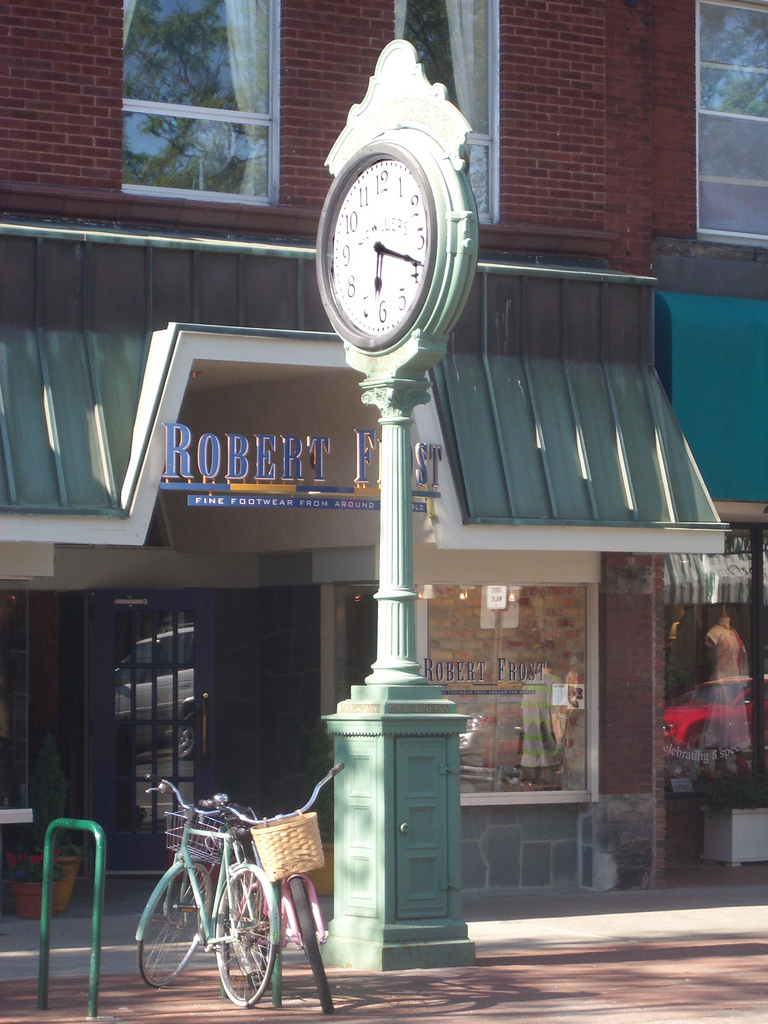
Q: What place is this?
A: It is a shop.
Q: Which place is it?
A: It is a shop.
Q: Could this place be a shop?
A: Yes, it is a shop.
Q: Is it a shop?
A: Yes, it is a shop.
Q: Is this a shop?
A: Yes, it is a shop.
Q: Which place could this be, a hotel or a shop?
A: It is a shop.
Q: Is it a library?
A: No, it is a shop.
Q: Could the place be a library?
A: No, it is a shop.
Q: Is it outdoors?
A: Yes, it is outdoors.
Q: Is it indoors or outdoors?
A: It is outdoors.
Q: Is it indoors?
A: No, it is outdoors.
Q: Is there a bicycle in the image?
A: Yes, there is a bicycle.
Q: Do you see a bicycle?
A: Yes, there is a bicycle.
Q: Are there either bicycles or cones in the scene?
A: Yes, there is a bicycle.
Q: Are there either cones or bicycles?
A: Yes, there is a bicycle.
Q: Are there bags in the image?
A: No, there are no bags.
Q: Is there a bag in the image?
A: No, there are no bags.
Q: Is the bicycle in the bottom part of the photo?
A: Yes, the bicycle is in the bottom of the image.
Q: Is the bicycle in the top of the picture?
A: No, the bicycle is in the bottom of the image.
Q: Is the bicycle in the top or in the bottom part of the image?
A: The bicycle is in the bottom of the image.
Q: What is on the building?
A: The sign is on the building.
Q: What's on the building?
A: The sign is on the building.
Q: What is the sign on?
A: The sign is on the building.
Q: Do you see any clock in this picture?
A: Yes, there is a clock.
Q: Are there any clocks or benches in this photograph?
A: Yes, there is a clock.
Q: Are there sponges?
A: No, there are no sponges.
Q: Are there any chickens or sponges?
A: No, there are no sponges or chickens.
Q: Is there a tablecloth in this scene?
A: No, there are no tablecloths.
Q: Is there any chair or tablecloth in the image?
A: No, there are no tablecloths or chairs.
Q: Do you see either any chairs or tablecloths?
A: No, there are no tablecloths or chairs.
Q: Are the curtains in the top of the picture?
A: Yes, the curtains are in the top of the image.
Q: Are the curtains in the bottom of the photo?
A: No, the curtains are in the top of the image.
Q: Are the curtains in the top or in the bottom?
A: The curtains are in the top of the image.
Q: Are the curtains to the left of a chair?
A: No, the curtains are to the left of the clock.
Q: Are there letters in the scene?
A: Yes, there are letters.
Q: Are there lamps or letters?
A: Yes, there are letters.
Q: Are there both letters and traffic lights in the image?
A: No, there are letters but no traffic lights.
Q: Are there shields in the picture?
A: No, there are no shields.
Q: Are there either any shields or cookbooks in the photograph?
A: No, there are no shields or cookbooks.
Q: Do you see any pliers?
A: No, there are no pliers.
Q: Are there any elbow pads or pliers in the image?
A: No, there are no pliers or elbow pads.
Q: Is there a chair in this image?
A: No, there are no chairs.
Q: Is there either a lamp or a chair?
A: No, there are no chairs or lamps.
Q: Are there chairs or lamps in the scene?
A: No, there are no chairs or lamps.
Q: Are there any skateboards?
A: No, there are no skateboards.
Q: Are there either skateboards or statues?
A: No, there are no skateboards or statues.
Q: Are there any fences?
A: No, there are no fences.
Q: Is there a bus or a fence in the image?
A: No, there are no fences or buses.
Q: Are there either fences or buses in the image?
A: No, there are no fences or buses.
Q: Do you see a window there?
A: Yes, there is a window.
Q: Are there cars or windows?
A: Yes, there is a window.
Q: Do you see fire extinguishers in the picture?
A: No, there are no fire extinguishers.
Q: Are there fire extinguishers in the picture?
A: No, there are no fire extinguishers.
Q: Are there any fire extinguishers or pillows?
A: No, there are no fire extinguishers or pillows.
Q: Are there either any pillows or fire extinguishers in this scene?
A: No, there are no fire extinguishers or pillows.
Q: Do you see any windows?
A: Yes, there is a window.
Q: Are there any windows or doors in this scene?
A: Yes, there is a window.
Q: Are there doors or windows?
A: Yes, there is a window.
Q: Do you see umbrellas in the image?
A: No, there are no umbrellas.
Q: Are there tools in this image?
A: No, there are no tools.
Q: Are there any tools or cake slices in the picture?
A: No, there are no tools or cake slices.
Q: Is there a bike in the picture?
A: Yes, there are bikes.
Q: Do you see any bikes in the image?
A: Yes, there are bikes.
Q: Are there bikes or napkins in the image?
A: Yes, there are bikes.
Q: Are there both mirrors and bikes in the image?
A: No, there are bikes but no mirrors.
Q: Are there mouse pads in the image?
A: No, there are no mouse pads.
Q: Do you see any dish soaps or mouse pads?
A: No, there are no mouse pads or dish soaps.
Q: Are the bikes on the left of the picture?
A: Yes, the bikes are on the left of the image.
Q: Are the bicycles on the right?
A: No, the bicycles are on the left of the image.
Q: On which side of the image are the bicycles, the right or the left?
A: The bicycles are on the left of the image.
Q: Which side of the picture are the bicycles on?
A: The bicycles are on the left of the image.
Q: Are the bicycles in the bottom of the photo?
A: Yes, the bicycles are in the bottom of the image.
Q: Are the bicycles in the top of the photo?
A: No, the bicycles are in the bottom of the image.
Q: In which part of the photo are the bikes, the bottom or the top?
A: The bikes are in the bottom of the image.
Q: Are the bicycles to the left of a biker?
A: No, the bicycles are to the left of the clock.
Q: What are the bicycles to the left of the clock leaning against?
A: The bicycles are leaning against the pole.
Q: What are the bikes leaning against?
A: The bicycles are leaning against the pole.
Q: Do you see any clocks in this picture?
A: Yes, there is a clock.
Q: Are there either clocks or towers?
A: Yes, there is a clock.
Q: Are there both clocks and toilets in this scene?
A: No, there is a clock but no toilets.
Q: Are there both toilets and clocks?
A: No, there is a clock but no toilets.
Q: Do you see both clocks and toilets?
A: No, there is a clock but no toilets.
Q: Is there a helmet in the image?
A: No, there are no helmets.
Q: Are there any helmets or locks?
A: No, there are no helmets or locks.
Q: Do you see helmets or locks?
A: No, there are no helmets or locks.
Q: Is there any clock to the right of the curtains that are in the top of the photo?
A: Yes, there is a clock to the right of the curtains.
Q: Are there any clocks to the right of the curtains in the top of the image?
A: Yes, there is a clock to the right of the curtains.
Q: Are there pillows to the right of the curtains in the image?
A: No, there is a clock to the right of the curtains.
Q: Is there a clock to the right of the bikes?
A: Yes, there is a clock to the right of the bikes.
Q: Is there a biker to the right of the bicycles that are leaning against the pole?
A: No, there is a clock to the right of the bikes.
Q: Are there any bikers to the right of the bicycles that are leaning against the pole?
A: No, there is a clock to the right of the bikes.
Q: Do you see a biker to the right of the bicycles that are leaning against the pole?
A: No, there is a clock to the right of the bikes.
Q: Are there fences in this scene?
A: No, there are no fences.